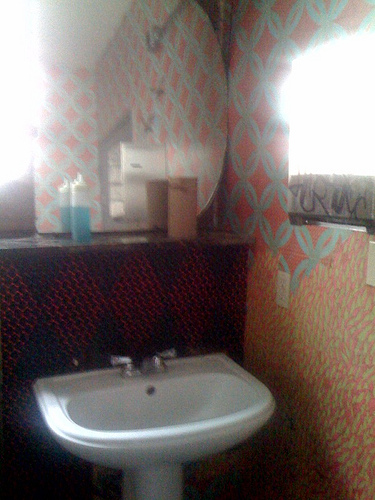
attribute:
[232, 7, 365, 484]
paper — decorative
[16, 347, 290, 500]
sink — white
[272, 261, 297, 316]
outlet — white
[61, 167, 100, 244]
bottle — blue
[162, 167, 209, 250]
paper roll — empty, carboard, brown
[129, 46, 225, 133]
diamonds — red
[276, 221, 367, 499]
wall — multicolored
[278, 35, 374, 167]
light — bright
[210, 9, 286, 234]
wall — orange, blue, red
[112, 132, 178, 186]
cap — white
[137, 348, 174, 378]
faucet — stainless steel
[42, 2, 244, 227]
mirror — round, large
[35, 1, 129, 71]
ceiling — white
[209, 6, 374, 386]
wallpaper — red, yellow